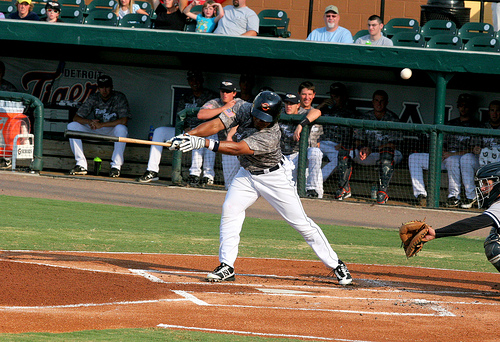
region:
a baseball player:
[98, 83, 359, 295]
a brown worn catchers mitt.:
[393, 204, 443, 269]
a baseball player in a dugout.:
[260, 83, 338, 200]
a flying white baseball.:
[393, 64, 423, 86]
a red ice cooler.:
[0, 91, 46, 170]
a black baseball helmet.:
[243, 82, 286, 132]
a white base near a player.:
[246, 281, 320, 313]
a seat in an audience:
[383, 10, 418, 39]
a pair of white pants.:
[208, 150, 347, 270]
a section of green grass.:
[0, 194, 499, 271]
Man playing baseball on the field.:
[165, 62, 450, 307]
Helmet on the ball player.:
[245, 87, 358, 164]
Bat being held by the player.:
[52, 89, 312, 230]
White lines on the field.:
[77, 250, 227, 336]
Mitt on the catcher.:
[372, 198, 474, 255]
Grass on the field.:
[85, 207, 321, 312]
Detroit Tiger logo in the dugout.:
[32, 49, 91, 131]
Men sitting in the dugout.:
[62, 81, 444, 228]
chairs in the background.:
[260, 5, 419, 61]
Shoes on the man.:
[80, 233, 412, 322]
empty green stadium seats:
[416, 10, 495, 50]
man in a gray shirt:
[358, 10, 403, 48]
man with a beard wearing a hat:
[304, 4, 366, 52]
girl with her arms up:
[181, 2, 229, 39]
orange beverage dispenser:
[2, 95, 44, 170]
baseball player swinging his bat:
[41, 61, 381, 306]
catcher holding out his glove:
[386, 152, 499, 297]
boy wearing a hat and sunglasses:
[41, 0, 73, 27]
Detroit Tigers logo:
[14, 58, 129, 156]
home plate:
[243, 266, 340, 311]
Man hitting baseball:
[149, 89, 362, 288]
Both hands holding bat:
[170, 123, 217, 159]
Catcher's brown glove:
[397, 210, 444, 256]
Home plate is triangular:
[251, 261, 316, 306]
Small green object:
[86, 152, 109, 170]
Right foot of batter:
[202, 257, 244, 287]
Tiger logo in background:
[23, 61, 113, 125]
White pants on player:
[220, 161, 336, 277]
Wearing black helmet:
[245, 92, 283, 124]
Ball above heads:
[393, 55, 430, 90]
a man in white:
[220, 28, 360, 292]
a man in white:
[207, 145, 300, 324]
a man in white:
[226, 100, 278, 317]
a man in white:
[213, 85, 288, 227]